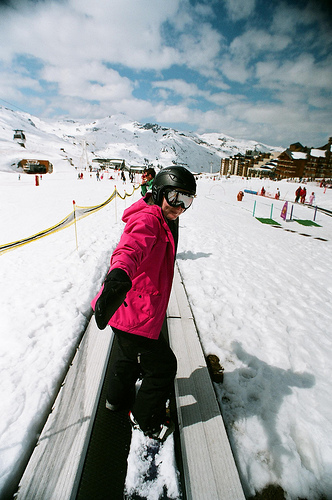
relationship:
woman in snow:
[90, 165, 197, 499] [1, 107, 332, 497]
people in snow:
[119, 159, 323, 212] [1, 107, 332, 497]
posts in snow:
[249, 198, 320, 227] [1, 107, 332, 497]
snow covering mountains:
[1, 107, 332, 497] [2, 103, 264, 174]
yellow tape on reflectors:
[1, 172, 136, 269] [69, 196, 81, 247]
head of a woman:
[153, 166, 198, 221] [90, 165, 197, 499]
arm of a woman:
[92, 223, 165, 329] [90, 165, 197, 499]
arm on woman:
[92, 223, 165, 329] [90, 165, 197, 499]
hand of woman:
[94, 271, 135, 331] [90, 165, 197, 499]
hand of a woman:
[94, 271, 135, 331] [90, 165, 197, 499]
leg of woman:
[126, 339, 179, 434] [90, 165, 197, 499]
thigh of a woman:
[127, 332, 177, 368] [90, 165, 197, 499]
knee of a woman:
[164, 343, 178, 382] [90, 165, 197, 499]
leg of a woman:
[126, 339, 179, 434] [90, 165, 197, 499]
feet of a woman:
[126, 407, 165, 460] [90, 165, 197, 499]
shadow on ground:
[178, 342, 317, 481] [1, 107, 332, 497]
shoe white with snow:
[129, 428, 178, 499] [1, 107, 332, 497]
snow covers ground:
[1, 107, 332, 497] [5, 172, 329, 496]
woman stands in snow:
[90, 165, 197, 499] [1, 107, 332, 497]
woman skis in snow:
[90, 165, 197, 499] [1, 107, 332, 497]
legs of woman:
[107, 330, 179, 434] [90, 165, 197, 499]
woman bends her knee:
[90, 165, 197, 499] [164, 343, 178, 382]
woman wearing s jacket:
[90, 165, 197, 499] [92, 193, 179, 340]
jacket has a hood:
[92, 193, 179, 340] [121, 194, 159, 215]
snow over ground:
[1, 107, 332, 497] [5, 172, 329, 496]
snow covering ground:
[1, 107, 332, 497] [5, 172, 329, 496]